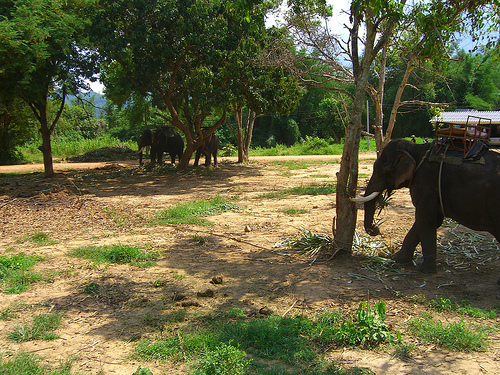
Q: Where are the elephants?
A: Under shade of trees.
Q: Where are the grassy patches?
A: In brown dirt.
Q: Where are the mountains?
A: In the distance.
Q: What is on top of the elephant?
A: An empty bench.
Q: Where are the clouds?
A: In the sky.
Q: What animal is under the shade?
A: An elephant.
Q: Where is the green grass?
A: On the ground.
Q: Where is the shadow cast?
A: On the ground.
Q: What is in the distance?
A: Trees.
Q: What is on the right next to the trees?
A: An elephant.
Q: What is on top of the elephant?
A: A seat.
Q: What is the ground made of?
A: Dirt and grass.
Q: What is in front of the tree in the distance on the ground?
A: A shadow.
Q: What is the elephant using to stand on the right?
A: Legs.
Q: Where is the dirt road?
A: Behind the elephants in the distance.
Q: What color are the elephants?
A: Gray.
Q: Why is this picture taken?
A: Photography.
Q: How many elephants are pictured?
A: 3.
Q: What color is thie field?
A: Green and brown.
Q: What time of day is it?
A: Day time.